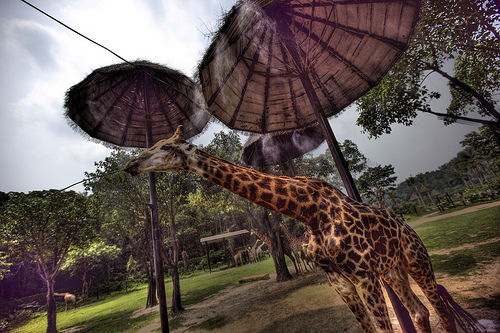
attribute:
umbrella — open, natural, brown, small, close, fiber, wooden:
[203, 5, 416, 134]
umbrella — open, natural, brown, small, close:
[63, 58, 213, 123]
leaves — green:
[10, 191, 97, 250]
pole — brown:
[311, 88, 350, 183]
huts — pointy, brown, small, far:
[409, 186, 439, 204]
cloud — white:
[8, 26, 57, 91]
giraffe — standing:
[250, 224, 266, 252]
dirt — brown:
[430, 205, 478, 222]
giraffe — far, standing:
[55, 289, 83, 313]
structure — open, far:
[198, 226, 255, 272]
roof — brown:
[198, 224, 257, 244]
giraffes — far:
[230, 238, 269, 266]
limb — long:
[430, 108, 483, 131]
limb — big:
[447, 65, 492, 109]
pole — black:
[201, 244, 219, 273]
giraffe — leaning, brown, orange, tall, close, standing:
[131, 127, 468, 325]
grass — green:
[97, 298, 127, 330]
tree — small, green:
[8, 184, 89, 330]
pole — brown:
[142, 191, 177, 328]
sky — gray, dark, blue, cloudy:
[394, 128, 445, 163]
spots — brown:
[196, 148, 272, 205]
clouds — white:
[9, 2, 206, 66]